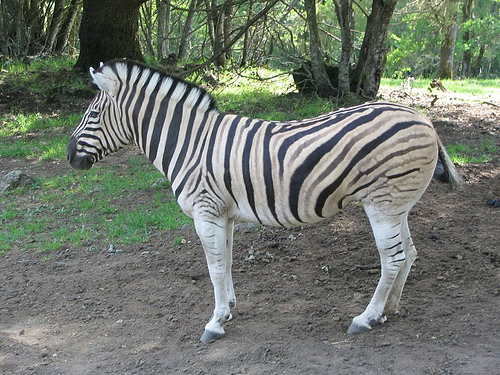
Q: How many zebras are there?
A: 1.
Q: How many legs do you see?
A: 4.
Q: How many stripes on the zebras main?
A: 10.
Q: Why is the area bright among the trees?
A: Sunshine.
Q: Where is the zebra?
A: The wild.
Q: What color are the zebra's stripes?
A: Black, white, grey.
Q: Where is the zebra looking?
A: Left.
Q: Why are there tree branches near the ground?
A: They fell.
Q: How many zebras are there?
A: 1.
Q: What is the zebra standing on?
A: Dirt.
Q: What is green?
A: Grass.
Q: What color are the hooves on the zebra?
A: They are a very dark black color.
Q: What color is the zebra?
A: The zebra has black and white stripes.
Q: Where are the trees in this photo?
A: There are trees directly behind the zebra.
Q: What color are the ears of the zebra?
A: The zebra's ears are primarily white.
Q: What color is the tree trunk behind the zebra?
A: The tree trunk is a dark brown color.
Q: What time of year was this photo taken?
A: Summer.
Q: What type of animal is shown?
A: Zebra.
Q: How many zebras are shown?
A: 1.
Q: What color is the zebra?
A: Black and white.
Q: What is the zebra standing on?
A: Dirt.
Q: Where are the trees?
A: Background.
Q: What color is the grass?
A: Green.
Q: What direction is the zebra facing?
A: Left.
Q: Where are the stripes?
A: On the zebra.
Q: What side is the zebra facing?
A: Left.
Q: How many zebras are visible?
A: One.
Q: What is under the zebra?
A: Dirt.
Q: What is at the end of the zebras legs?
A: Hooves.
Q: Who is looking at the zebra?
A: The photographer.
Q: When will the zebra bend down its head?
A: When it wants to chew some grass.